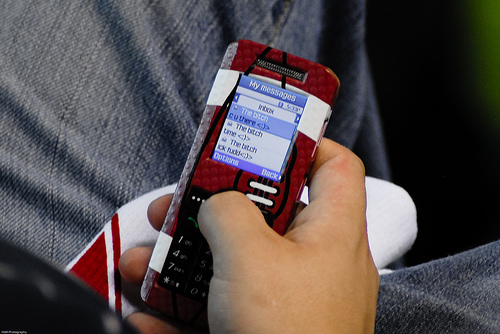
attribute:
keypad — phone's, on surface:
[159, 188, 279, 308]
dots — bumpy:
[164, 118, 204, 201]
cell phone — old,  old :
[133, 25, 348, 332]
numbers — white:
[159, 231, 191, 274]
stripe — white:
[246, 178, 278, 195]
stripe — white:
[244, 188, 278, 208]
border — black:
[231, 140, 295, 221]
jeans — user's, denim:
[10, 10, 410, 270]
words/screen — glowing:
[217, 70, 300, 189]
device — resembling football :
[140, 30, 327, 315]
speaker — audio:
[255, 59, 305, 80]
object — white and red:
[52, 173, 419, 318]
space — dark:
[371, 16, 498, 175]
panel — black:
[156, 185, 229, 229]